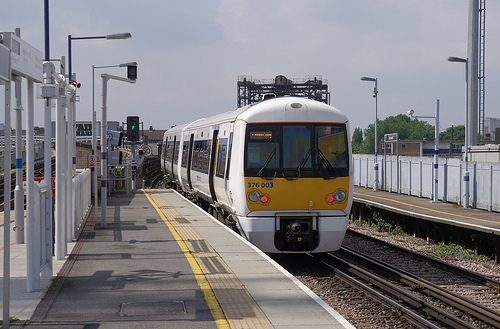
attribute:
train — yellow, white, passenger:
[101, 89, 354, 303]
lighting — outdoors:
[91, 21, 153, 84]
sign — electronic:
[242, 124, 277, 146]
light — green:
[123, 106, 153, 139]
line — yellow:
[141, 178, 227, 327]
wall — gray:
[360, 140, 498, 209]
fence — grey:
[368, 155, 493, 193]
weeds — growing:
[355, 203, 423, 246]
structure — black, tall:
[225, 64, 356, 104]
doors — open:
[146, 126, 224, 194]